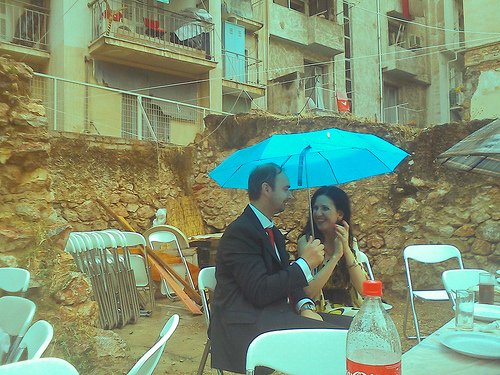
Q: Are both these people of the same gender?
A: No, they are both male and female.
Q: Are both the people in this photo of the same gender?
A: No, they are both male and female.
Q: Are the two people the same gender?
A: No, they are both male and female.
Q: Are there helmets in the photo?
A: No, there are no helmets.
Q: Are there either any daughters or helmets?
A: No, there are no helmets or daughters.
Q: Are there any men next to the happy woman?
A: Yes, there is a man next to the woman.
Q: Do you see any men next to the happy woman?
A: Yes, there is a man next to the woman.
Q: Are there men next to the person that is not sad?
A: Yes, there is a man next to the woman.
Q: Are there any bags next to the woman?
A: No, there is a man next to the woman.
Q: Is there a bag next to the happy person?
A: No, there is a man next to the woman.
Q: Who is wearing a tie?
A: The man is wearing a tie.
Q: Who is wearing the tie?
A: The man is wearing a tie.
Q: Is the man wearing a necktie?
A: Yes, the man is wearing a necktie.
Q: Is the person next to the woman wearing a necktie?
A: Yes, the man is wearing a necktie.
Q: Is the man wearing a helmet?
A: No, the man is wearing a necktie.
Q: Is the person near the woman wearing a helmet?
A: No, the man is wearing a necktie.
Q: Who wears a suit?
A: The man wears a suit.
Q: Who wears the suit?
A: The man wears a suit.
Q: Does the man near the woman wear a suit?
A: Yes, the man wears a suit.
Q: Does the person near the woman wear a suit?
A: Yes, the man wears a suit.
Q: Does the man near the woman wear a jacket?
A: No, the man wears a suit.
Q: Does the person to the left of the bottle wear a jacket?
A: No, the man wears a suit.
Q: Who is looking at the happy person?
A: The man is looking at the woman.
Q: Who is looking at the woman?
A: The man is looking at the woman.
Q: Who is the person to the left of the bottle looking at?
A: The man is looking at the woman.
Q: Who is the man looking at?
A: The man is looking at the woman.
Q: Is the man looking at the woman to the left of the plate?
A: Yes, the man is looking at the woman.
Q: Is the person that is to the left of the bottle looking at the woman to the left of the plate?
A: Yes, the man is looking at the woman.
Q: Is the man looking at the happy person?
A: Yes, the man is looking at the woman.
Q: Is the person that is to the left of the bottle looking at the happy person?
A: Yes, the man is looking at the woman.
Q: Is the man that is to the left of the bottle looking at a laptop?
A: No, the man is looking at the woman.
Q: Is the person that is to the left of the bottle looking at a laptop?
A: No, the man is looking at the woman.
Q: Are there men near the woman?
A: Yes, there is a man near the woman.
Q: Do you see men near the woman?
A: Yes, there is a man near the woman.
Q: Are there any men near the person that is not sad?
A: Yes, there is a man near the woman.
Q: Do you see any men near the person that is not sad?
A: Yes, there is a man near the woman.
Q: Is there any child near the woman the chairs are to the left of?
A: No, there is a man near the woman.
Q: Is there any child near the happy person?
A: No, there is a man near the woman.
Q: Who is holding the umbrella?
A: The man is holding the umbrella.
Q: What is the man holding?
A: The man is holding the umbrella.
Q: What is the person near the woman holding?
A: The man is holding the umbrella.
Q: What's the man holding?
A: The man is holding the umbrella.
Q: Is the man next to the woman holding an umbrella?
A: Yes, the man is holding an umbrella.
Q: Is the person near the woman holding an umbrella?
A: Yes, the man is holding an umbrella.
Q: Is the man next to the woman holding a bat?
A: No, the man is holding an umbrella.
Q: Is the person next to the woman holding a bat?
A: No, the man is holding an umbrella.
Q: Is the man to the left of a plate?
A: Yes, the man is to the left of a plate.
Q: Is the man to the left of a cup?
A: No, the man is to the left of a plate.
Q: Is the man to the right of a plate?
A: No, the man is to the left of a plate.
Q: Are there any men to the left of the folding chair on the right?
A: Yes, there is a man to the left of the folding chair.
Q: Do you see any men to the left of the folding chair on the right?
A: Yes, there is a man to the left of the folding chair.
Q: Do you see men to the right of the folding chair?
A: No, the man is to the left of the folding chair.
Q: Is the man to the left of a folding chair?
A: Yes, the man is to the left of a folding chair.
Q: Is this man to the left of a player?
A: No, the man is to the left of a folding chair.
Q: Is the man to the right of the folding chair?
A: No, the man is to the left of the folding chair.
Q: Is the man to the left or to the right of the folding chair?
A: The man is to the left of the folding chair.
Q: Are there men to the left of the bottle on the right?
A: Yes, there is a man to the left of the bottle.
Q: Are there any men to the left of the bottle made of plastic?
A: Yes, there is a man to the left of the bottle.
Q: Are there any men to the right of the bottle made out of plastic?
A: No, the man is to the left of the bottle.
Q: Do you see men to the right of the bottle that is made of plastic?
A: No, the man is to the left of the bottle.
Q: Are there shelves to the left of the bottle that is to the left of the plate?
A: No, there is a man to the left of the bottle.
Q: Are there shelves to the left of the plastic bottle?
A: No, there is a man to the left of the bottle.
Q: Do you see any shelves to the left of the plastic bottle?
A: No, there is a man to the left of the bottle.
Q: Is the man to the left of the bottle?
A: Yes, the man is to the left of the bottle.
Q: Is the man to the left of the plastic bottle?
A: Yes, the man is to the left of the bottle.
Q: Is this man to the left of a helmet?
A: No, the man is to the left of the bottle.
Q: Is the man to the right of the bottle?
A: No, the man is to the left of the bottle.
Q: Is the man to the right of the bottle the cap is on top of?
A: No, the man is to the left of the bottle.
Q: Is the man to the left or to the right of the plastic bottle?
A: The man is to the left of the bottle.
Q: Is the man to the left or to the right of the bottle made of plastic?
A: The man is to the left of the bottle.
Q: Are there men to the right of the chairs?
A: Yes, there is a man to the right of the chairs.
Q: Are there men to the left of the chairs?
A: No, the man is to the right of the chairs.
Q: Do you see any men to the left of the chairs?
A: No, the man is to the right of the chairs.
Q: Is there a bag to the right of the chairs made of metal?
A: No, there is a man to the right of the chairs.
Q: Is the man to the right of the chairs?
A: Yes, the man is to the right of the chairs.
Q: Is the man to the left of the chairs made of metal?
A: No, the man is to the right of the chairs.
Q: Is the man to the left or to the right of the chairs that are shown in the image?
A: The man is to the right of the chairs.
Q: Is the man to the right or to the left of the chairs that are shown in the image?
A: The man is to the right of the chairs.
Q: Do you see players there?
A: No, there are no players.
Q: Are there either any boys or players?
A: No, there are no players or boys.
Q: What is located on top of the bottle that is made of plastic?
A: The cap is on top of the bottle.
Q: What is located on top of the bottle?
A: The cap is on top of the bottle.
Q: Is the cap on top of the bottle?
A: Yes, the cap is on top of the bottle.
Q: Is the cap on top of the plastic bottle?
A: Yes, the cap is on top of the bottle.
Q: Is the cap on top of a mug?
A: No, the cap is on top of the bottle.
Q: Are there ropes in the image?
A: No, there are no ropes.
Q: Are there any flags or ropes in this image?
A: No, there are no ropes or flags.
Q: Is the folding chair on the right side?
A: Yes, the folding chair is on the right of the image.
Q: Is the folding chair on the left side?
A: No, the folding chair is on the right of the image.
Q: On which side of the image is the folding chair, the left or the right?
A: The folding chair is on the right of the image.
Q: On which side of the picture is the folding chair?
A: The folding chair is on the right of the image.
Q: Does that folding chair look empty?
A: Yes, the folding chair is empty.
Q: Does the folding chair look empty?
A: Yes, the folding chair is empty.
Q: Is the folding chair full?
A: No, the folding chair is empty.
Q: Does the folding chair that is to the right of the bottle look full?
A: No, the folding chair is empty.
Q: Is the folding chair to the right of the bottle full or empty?
A: The folding chair is empty.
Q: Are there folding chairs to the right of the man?
A: Yes, there is a folding chair to the right of the man.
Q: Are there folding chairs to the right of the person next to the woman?
A: Yes, there is a folding chair to the right of the man.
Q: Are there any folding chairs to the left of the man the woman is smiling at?
A: No, the folding chair is to the right of the man.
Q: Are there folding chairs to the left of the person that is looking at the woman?
A: No, the folding chair is to the right of the man.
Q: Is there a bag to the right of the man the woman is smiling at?
A: No, there is a folding chair to the right of the man.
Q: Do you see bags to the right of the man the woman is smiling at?
A: No, there is a folding chair to the right of the man.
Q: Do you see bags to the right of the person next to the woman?
A: No, there is a folding chair to the right of the man.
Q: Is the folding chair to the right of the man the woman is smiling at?
A: Yes, the folding chair is to the right of the man.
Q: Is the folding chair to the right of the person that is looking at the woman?
A: Yes, the folding chair is to the right of the man.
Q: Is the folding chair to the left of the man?
A: No, the folding chair is to the right of the man.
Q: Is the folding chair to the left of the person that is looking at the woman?
A: No, the folding chair is to the right of the man.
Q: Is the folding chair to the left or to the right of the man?
A: The folding chair is to the right of the man.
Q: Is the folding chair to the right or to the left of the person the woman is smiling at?
A: The folding chair is to the right of the man.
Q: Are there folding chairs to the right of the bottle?
A: Yes, there is a folding chair to the right of the bottle.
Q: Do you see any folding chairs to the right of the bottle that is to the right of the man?
A: Yes, there is a folding chair to the right of the bottle.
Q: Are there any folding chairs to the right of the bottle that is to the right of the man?
A: Yes, there is a folding chair to the right of the bottle.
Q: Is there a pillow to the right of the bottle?
A: No, there is a folding chair to the right of the bottle.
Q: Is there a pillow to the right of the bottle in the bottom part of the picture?
A: No, there is a folding chair to the right of the bottle.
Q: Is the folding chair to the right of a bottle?
A: Yes, the folding chair is to the right of a bottle.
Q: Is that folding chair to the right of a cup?
A: No, the folding chair is to the right of a bottle.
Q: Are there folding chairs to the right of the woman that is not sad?
A: Yes, there is a folding chair to the right of the woman.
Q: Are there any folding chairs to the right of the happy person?
A: Yes, there is a folding chair to the right of the woman.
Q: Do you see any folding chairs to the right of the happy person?
A: Yes, there is a folding chair to the right of the woman.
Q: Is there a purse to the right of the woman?
A: No, there is a folding chair to the right of the woman.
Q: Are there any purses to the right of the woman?
A: No, there is a folding chair to the right of the woman.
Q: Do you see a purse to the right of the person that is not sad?
A: No, there is a folding chair to the right of the woman.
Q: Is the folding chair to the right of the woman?
A: Yes, the folding chair is to the right of the woman.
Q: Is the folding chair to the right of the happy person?
A: Yes, the folding chair is to the right of the woman.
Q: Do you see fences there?
A: Yes, there is a fence.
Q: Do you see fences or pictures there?
A: Yes, there is a fence.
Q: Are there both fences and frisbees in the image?
A: No, there is a fence but no frisbees.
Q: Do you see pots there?
A: No, there are no pots.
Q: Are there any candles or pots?
A: No, there are no pots or candles.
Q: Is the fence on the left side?
A: Yes, the fence is on the left of the image.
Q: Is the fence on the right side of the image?
A: No, the fence is on the left of the image.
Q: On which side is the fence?
A: The fence is on the left of the image.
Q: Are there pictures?
A: No, there are no pictures.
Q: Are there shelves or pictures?
A: No, there are no pictures or shelves.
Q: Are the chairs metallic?
A: Yes, the chairs are metallic.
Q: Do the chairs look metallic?
A: Yes, the chairs are metallic.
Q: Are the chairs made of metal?
A: Yes, the chairs are made of metal.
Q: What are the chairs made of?
A: The chairs are made of metal.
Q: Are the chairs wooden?
A: No, the chairs are metallic.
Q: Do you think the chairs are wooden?
A: No, the chairs are metallic.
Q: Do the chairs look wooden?
A: No, the chairs are metallic.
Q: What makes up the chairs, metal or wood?
A: The chairs are made of metal.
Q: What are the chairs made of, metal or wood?
A: The chairs are made of metal.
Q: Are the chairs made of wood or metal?
A: The chairs are made of metal.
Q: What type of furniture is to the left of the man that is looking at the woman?
A: The pieces of furniture are chairs.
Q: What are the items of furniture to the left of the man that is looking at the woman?
A: The pieces of furniture are chairs.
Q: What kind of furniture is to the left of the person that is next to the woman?
A: The pieces of furniture are chairs.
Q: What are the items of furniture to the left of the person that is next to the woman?
A: The pieces of furniture are chairs.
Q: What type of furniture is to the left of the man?
A: The pieces of furniture are chairs.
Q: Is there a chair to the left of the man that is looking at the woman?
A: Yes, there are chairs to the left of the man.